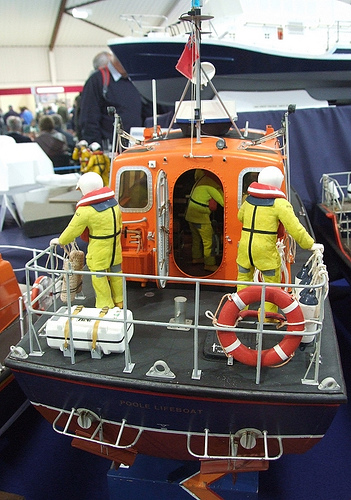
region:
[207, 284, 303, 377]
red life saver on boat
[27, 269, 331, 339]
white guard rail over boat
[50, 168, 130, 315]
a worker on the boat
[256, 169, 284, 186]
white helmet on man's head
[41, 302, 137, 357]
white case on back of boat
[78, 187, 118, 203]
red life vest on workers neck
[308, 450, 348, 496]
blue flooring on the ground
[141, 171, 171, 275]
door into the boat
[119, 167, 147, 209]
window on back of boat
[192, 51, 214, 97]
white speaker on top of boat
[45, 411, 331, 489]
two handles are on the back of the boat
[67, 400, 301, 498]
the handles are secured with screws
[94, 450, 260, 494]
a blue box is on the boat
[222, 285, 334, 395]
a life saving tool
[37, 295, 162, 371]
a first aid kit is on the boat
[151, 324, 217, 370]
the deck is gray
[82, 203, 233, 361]
the crew wears green suits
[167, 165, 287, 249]
the man is in the galley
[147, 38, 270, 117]
a flag hangs from the pole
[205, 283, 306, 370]
Orange and white lifesaver.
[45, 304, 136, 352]
A white plastic case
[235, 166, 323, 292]
A person dressed in yellow.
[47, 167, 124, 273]
A person wearing a safety helmet.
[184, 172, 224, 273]
A person in a boat cabin.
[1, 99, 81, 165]
A crowd of people.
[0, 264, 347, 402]
A dark gray boat deck.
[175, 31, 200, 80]
A small red flag.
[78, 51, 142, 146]
A person wearing blue.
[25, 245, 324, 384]
A silver metal railing.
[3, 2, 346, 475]
blue, black and orange rescue boat on display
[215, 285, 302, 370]
red and white life rescue ring with rope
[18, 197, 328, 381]
gray metal rail around the perimeter of the boat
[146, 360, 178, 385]
gray metal ring to tie boats to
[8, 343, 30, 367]
blue and white flowers with greens in a clear vase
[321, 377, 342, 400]
blue and white flowers with greens in a clear vase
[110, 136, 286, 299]
orange cabin on a rescue boat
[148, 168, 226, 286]
door to orange cabin on a rescue boat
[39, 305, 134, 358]
white case possibly for first aid equipment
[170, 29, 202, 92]
red flag on a gray metal pole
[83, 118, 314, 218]
the boat is orange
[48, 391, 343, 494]
the boat has silver handles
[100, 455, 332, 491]
the box is blue and orange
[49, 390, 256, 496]
the colors are blue and red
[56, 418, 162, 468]
bags are underneath the handle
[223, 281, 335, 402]
a life vessel is orange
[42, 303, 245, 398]
a white box is on the boat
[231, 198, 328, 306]
the man is in a yellow suit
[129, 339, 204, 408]
white handles are on the boat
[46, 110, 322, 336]
the boat is a figurine